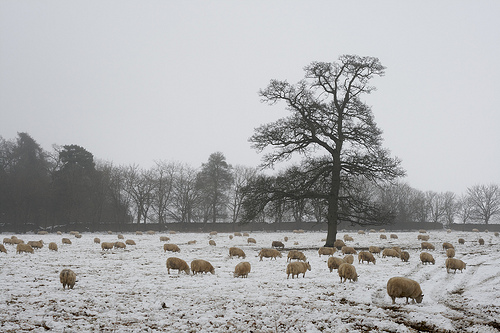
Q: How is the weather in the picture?
A: It is cloudy.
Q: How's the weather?
A: It is cloudy.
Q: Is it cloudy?
A: Yes, it is cloudy.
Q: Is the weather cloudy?
A: Yes, it is cloudy.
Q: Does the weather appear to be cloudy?
A: Yes, it is cloudy.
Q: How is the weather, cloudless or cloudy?
A: It is cloudy.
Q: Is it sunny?
A: No, it is cloudy.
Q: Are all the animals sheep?
A: Yes, all the animals are sheep.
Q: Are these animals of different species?
A: No, all the animals are sheep.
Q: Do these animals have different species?
A: No, all the animals are sheep.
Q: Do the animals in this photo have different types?
A: No, all the animals are sheep.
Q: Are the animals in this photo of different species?
A: No, all the animals are sheep.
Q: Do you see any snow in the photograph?
A: Yes, there is snow.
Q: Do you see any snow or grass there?
A: Yes, there is snow.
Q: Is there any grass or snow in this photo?
A: Yes, there is snow.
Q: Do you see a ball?
A: No, there are no balls.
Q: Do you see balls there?
A: No, there are no balls.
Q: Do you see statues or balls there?
A: No, there are no balls or statues.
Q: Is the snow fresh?
A: Yes, the snow is fresh.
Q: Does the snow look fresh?
A: Yes, the snow is fresh.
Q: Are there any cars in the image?
A: No, there are no cars.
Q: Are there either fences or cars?
A: No, there are no cars or fences.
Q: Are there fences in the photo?
A: No, there are no fences.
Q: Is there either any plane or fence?
A: No, there are no fences or airplanes.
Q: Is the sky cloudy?
A: Yes, the sky is cloudy.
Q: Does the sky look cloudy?
A: Yes, the sky is cloudy.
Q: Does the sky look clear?
A: No, the sky is cloudy.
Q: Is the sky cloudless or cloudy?
A: The sky is cloudy.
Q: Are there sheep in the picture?
A: Yes, there is a sheep.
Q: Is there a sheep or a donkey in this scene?
A: Yes, there is a sheep.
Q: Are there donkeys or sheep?
A: Yes, there is a sheep.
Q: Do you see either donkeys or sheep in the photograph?
A: Yes, there is a sheep.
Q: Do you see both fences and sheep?
A: No, there is a sheep but no fences.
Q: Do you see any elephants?
A: No, there are no elephants.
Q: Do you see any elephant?
A: No, there are no elephants.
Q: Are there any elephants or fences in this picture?
A: No, there are no elephants or fences.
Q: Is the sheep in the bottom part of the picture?
A: Yes, the sheep is in the bottom of the image.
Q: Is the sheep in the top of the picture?
A: No, the sheep is in the bottom of the image.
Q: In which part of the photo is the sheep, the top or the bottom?
A: The sheep is in the bottom of the image.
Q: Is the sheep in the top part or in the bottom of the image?
A: The sheep is in the bottom of the image.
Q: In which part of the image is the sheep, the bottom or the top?
A: The sheep is in the bottom of the image.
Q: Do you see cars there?
A: No, there are no cars.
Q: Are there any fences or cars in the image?
A: No, there are no cars or fences.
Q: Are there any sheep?
A: Yes, there is a sheep.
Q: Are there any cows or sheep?
A: Yes, there is a sheep.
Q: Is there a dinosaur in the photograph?
A: No, there are no dinosaurs.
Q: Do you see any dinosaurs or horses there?
A: No, there are no dinosaurs or horses.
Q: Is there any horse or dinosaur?
A: No, there are no dinosaurs or horses.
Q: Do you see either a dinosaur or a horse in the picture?
A: No, there are no dinosaurs or horses.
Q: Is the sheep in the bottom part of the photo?
A: Yes, the sheep is in the bottom of the image.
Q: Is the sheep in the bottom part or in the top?
A: The sheep is in the bottom of the image.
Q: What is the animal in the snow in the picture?
A: The animal is a sheep.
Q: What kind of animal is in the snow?
A: The animal is a sheep.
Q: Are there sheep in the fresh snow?
A: Yes, there is a sheep in the snow.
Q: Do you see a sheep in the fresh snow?
A: Yes, there is a sheep in the snow.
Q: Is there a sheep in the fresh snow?
A: Yes, there is a sheep in the snow.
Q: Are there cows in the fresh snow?
A: No, there is a sheep in the snow.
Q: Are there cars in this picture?
A: No, there are no cars.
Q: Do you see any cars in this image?
A: No, there are no cars.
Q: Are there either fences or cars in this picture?
A: No, there are no cars or fences.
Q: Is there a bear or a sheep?
A: Yes, there is a sheep.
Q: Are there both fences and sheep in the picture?
A: No, there is a sheep but no fences.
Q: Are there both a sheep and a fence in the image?
A: No, there is a sheep but no fences.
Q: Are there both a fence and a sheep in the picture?
A: No, there is a sheep but no fences.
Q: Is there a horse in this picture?
A: No, there are no horses.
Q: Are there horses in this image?
A: No, there are no horses.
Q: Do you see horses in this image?
A: No, there are no horses.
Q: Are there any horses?
A: No, there are no horses.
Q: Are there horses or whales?
A: No, there are no horses or whales.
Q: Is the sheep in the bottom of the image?
A: Yes, the sheep is in the bottom of the image.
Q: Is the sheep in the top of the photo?
A: No, the sheep is in the bottom of the image.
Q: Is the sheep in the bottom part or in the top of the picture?
A: The sheep is in the bottom of the image.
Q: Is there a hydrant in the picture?
A: No, there are no fire hydrants.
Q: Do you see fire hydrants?
A: No, there are no fire hydrants.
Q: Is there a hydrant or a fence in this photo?
A: No, there are no fire hydrants or fences.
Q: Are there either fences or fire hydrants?
A: No, there are no fire hydrants or fences.